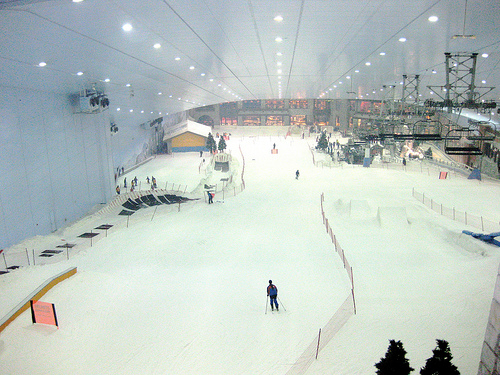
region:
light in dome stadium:
[29, 52, 50, 80]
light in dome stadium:
[66, 60, 85, 87]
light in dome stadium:
[100, 68, 111, 86]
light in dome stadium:
[142, 35, 166, 56]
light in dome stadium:
[163, 49, 181, 67]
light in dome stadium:
[263, 8, 292, 25]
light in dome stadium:
[270, 29, 294, 48]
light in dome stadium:
[272, 46, 287, 59]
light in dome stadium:
[422, 10, 445, 32]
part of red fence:
[418, 193, 431, 215]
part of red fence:
[428, 195, 440, 220]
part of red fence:
[439, 201, 456, 218]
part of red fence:
[476, 210, 498, 241]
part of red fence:
[264, 324, 329, 374]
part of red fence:
[311, 283, 362, 353]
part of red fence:
[336, 255, 367, 313]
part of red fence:
[331, 236, 357, 273]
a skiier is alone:
[252, 263, 307, 318]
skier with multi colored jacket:
[254, 273, 299, 333]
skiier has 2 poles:
[254, 280, 301, 327]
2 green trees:
[373, 332, 446, 371]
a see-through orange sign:
[23, 287, 90, 349]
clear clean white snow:
[133, 241, 228, 346]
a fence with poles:
[296, 193, 378, 337]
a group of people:
[106, 169, 168, 216]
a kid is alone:
[199, 183, 228, 211]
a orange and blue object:
[421, 160, 487, 190]